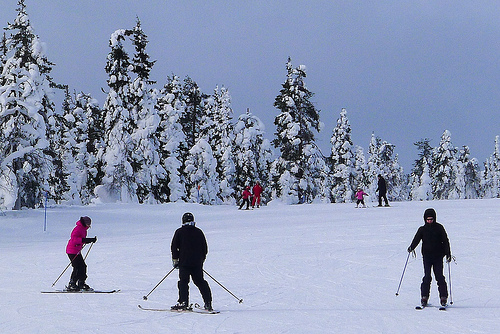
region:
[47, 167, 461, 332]
a group of people on skis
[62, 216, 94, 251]
a person in a pink winter coat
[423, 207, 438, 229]
a person with a coat hood on their head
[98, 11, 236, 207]
evergreen trees with a large amount of snow on them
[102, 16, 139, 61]
a tree top bending under the weight of the snow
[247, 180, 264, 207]
a person dressed in a red snow suit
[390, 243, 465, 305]
a person holding ski poles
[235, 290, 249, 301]
the tip of a ski pole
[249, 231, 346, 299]
ski tracks in the snow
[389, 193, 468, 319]
Skier on the snow.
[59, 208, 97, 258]
Pink jacket on person.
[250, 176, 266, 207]
Red jacket on the person.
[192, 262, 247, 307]
ski pole in the hand.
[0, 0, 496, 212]
Trees in the background.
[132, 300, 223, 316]
Skis on the snow.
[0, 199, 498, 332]
snow covering the ground.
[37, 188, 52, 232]
blue pole in the ground.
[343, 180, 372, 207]
child on the snow.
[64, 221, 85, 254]
a pink coat on a person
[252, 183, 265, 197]
a red coat on a person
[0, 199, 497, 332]
a white snowy slope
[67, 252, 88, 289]
black pants on a person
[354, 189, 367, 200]
a pink coat on a child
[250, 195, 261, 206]
red pants on a person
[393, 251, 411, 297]
a ski pole in a person's hand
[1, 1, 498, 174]
a grey blue sky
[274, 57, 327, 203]
a snow covered pine tree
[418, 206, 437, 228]
a black hood over a person's head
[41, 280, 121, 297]
Woman on skis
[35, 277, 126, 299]
Woman is on skis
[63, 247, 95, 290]
Woman wearing pants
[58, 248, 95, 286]
Woman is wearing pants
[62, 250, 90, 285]
Woman wearing black pants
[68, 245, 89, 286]
Woman is wearing black pants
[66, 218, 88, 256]
Woman wearing a jacket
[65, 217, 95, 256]
Woman is wearing a jacket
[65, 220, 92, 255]
Woman wearing a pink jacket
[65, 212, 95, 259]
a puffy bright pink snow jacket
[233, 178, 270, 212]
a pair of skiers in bright red outfits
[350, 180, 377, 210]
a small child in a bright pink jacket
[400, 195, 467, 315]
a person all in black on skis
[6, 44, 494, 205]
a large amount of trees covered in snow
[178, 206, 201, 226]
a shiny black ski helmet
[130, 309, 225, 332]
a few ski tracks in the snow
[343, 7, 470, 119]
a thick layer of gray in the sky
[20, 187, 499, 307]
a flat plain of snow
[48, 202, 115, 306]
skier in white snow on hillside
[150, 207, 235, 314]
skier in white snow on hillside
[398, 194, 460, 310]
skier in white snow on hillside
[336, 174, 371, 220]
skier in white snow on hillside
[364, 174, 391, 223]
skier in white snow on hillside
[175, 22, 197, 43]
white clouds in blue sky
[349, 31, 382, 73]
white clouds in blue sky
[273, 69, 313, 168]
tree covered in white snow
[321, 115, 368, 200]
tree covered in white snow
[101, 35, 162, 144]
tree covered in white snow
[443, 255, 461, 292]
a long trekking pole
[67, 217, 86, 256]
a woman's pink snow jacket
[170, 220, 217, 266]
a man's black jacket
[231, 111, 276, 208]
a tall snow covered tree